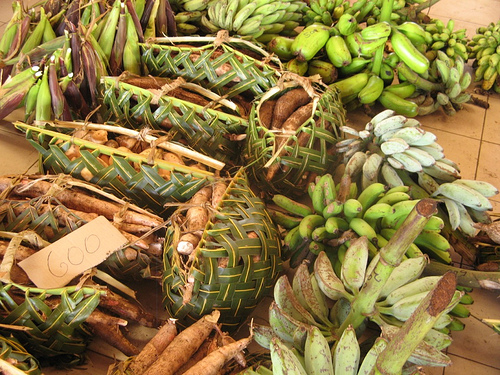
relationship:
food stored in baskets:
[70, 58, 439, 307] [17, 27, 352, 210]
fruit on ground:
[10, 9, 452, 367] [2, 3, 499, 373]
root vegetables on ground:
[10, 4, 366, 373] [2, 3, 499, 373]